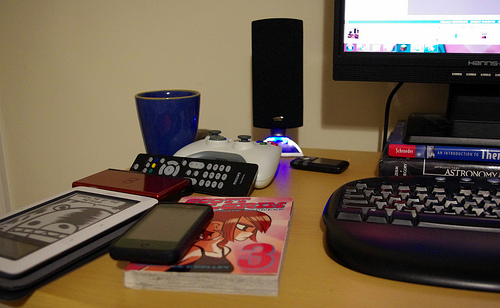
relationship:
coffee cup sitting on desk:
[129, 88, 204, 158] [4, 128, 492, 301]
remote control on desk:
[128, 150, 261, 199] [4, 128, 492, 301]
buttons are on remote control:
[198, 163, 229, 187] [124, 149, 256, 196]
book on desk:
[374, 153, 498, 187] [4, 128, 492, 301]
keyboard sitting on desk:
[333, 175, 497, 244] [4, 128, 492, 301]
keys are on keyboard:
[395, 183, 489, 217] [319, 172, 498, 301]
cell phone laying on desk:
[105, 193, 212, 259] [12, 142, 492, 304]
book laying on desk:
[146, 185, 288, 294] [12, 142, 492, 304]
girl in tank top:
[165, 205, 277, 272] [159, 240, 233, 272]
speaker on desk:
[248, 13, 303, 130] [4, 128, 492, 301]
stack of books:
[379, 126, 498, 176] [379, 131, 495, 184]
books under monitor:
[379, 131, 495, 184] [335, 3, 495, 138]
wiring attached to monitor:
[376, 82, 403, 149] [335, 3, 495, 138]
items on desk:
[1, 2, 498, 305] [4, 128, 492, 301]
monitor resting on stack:
[335, 3, 495, 138] [378, 126, 498, 179]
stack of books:
[378, 126, 498, 179] [370, 134, 498, 180]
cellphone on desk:
[288, 152, 349, 174] [12, 142, 492, 304]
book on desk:
[116, 188, 298, 298] [12, 142, 492, 304]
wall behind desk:
[1, 0, 449, 217] [12, 142, 492, 304]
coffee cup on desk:
[133, 88, 201, 158] [12, 142, 492, 304]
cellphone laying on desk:
[288, 152, 358, 177] [12, 142, 492, 304]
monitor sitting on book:
[331, 0, 499, 89] [384, 119, 498, 163]